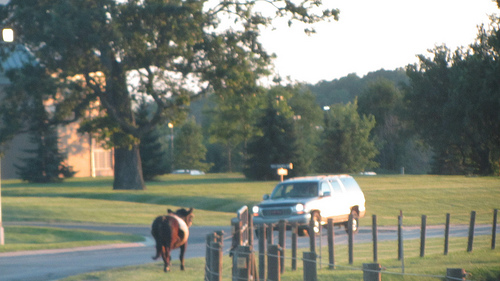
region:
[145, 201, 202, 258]
an animal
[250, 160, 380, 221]
an SUV in the road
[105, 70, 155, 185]
a tree trunk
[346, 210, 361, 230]
the back tire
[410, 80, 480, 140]
green bushes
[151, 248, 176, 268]
the animals legs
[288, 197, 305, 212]
the lights on SUV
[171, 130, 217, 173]
a green tree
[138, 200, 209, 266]
the animal is standing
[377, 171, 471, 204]
The lawn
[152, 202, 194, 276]
animal on side of road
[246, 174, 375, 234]
car with headlights on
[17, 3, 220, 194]
tall tree with leaves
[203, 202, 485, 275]
fence made of wooden poles and wire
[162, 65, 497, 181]
forest in the background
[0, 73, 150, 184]
red building in background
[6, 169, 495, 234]
short grass covered area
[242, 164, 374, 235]
white colored car with brown rims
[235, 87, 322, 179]
tall triangle pine tree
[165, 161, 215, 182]
blue object in background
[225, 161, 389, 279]
car driving on a road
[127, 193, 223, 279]
cow running toward a car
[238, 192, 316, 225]
lit round headlights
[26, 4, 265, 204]
tall tree with a thick trunk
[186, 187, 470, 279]
fence with wooden posts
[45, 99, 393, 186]
group of short pine trees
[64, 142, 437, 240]
neatly mowed grass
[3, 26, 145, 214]
a house hidden by trees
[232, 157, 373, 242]
older style of a vehicle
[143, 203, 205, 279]
brown animal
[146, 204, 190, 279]
Large brown cow walking down road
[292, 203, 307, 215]
Headlight on front on suv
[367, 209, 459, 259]
Group of brown wooden poles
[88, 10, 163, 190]
Large green tree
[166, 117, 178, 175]
Tall metal street light thats turned on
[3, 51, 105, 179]
Large brick building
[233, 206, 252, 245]
Rusted colored metal gate attached to fence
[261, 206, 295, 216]
Grey grill on front of suv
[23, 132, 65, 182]
Small pine tree in front of building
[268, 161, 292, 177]
Street sign behind vehicle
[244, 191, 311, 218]
the headlights are on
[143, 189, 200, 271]
an animal is running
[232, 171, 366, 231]
the car is moving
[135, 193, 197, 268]
the animal is brown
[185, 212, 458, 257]
the fence is short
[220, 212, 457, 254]
the fence poles are made of wood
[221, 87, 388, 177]
trees behind the car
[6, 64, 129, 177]
building behind the tree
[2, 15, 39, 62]
a light through the trees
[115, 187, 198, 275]
the animal is on the grass